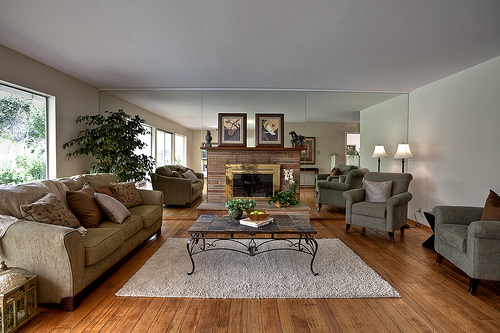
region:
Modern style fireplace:
[199, 144, 311, 221]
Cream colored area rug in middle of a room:
[112, 232, 403, 299]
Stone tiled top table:
[185, 212, 320, 277]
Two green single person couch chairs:
[340, 169, 499, 296]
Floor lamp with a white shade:
[394, 140, 414, 175]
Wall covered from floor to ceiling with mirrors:
[91, 85, 411, 223]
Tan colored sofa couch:
[3, 168, 165, 315]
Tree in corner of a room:
[62, 106, 157, 191]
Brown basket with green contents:
[246, 206, 268, 222]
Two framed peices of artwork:
[215, 111, 286, 149]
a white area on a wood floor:
[111, 232, 408, 302]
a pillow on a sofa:
[23, 188, 78, 238]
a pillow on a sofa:
[109, 178, 144, 209]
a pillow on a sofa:
[63, 179, 103, 227]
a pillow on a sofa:
[90, 188, 132, 223]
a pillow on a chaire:
[356, 172, 395, 206]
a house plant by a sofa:
[78, 107, 150, 180]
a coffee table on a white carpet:
[183, 203, 334, 280]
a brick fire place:
[200, 142, 312, 211]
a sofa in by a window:
[150, 154, 207, 210]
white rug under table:
[110, 242, 389, 300]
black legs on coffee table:
[158, 238, 320, 275]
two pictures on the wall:
[207, 108, 288, 155]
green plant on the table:
[228, 190, 250, 250]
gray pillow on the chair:
[346, 170, 388, 210]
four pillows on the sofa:
[18, 174, 147, 240]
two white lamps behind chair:
[366, 142, 433, 179]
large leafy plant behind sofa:
[72, 108, 145, 188]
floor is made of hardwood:
[72, 303, 487, 331]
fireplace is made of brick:
[203, 146, 298, 211]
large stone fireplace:
[202, 145, 304, 207]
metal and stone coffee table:
[187, 211, 320, 276]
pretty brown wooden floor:
[103, 302, 495, 329]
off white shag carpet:
[121, 224, 398, 296]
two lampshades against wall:
[368, 139, 415, 162]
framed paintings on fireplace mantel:
[217, 112, 284, 146]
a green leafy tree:
[60, 106, 147, 183]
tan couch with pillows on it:
[1, 167, 166, 310]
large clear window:
[1, 79, 59, 184]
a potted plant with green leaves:
[224, 197, 254, 214]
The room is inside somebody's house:
[2, 45, 489, 325]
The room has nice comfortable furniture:
[2, 45, 487, 321]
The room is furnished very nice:
[6, 45, 494, 331]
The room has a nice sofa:
[3, 52, 489, 317]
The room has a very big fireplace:
[6, 40, 496, 320]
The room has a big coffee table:
[5, 32, 480, 317]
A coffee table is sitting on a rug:
[176, 195, 346, 292]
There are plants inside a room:
[10, 22, 480, 308]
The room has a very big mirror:
[13, 30, 473, 323]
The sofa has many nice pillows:
[2, 153, 177, 326]